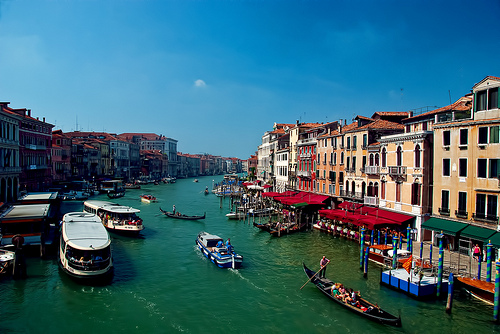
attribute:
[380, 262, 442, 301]
boat — blue, white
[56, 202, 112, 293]
boat — large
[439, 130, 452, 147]
window — glass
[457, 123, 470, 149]
window — glass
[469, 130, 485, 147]
window — glass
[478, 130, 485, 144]
window — glass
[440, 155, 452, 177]
window — glass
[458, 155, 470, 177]
window — glass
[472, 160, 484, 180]
window — glass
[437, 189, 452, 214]
window — glass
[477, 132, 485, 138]
window — glass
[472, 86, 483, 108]
window — glass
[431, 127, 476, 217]
window — glass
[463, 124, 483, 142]
window — glass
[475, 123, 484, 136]
window — glass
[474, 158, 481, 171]
window — glass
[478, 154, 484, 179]
window — glass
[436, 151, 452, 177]
window — glass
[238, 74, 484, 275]
building — orange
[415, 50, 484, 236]
building — glass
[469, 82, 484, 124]
window — glass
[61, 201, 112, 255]
top — white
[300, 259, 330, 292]
paddle — wood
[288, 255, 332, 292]
paddle — brown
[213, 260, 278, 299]
trail — water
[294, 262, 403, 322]
boat — blue, white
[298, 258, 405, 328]
boat — blue, white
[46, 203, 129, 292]
boat — white, blue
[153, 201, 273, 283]
boat — blue, white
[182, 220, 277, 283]
boat — white, blue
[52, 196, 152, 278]
boat — blue, white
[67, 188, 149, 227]
boat — white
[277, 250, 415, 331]
gondola — filled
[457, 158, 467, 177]
window — glass